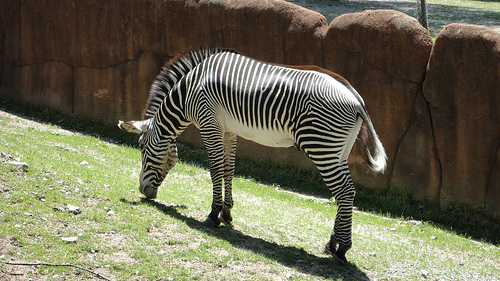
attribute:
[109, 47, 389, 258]
zebra — grazing, alone, black, white, eating, standing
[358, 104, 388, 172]
tail — fuzzy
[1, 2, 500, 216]
wall — brown, false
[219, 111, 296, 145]
belly — white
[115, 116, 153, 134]
ear — big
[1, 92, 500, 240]
shadow — dark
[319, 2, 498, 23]
fence — metal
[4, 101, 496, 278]
ground — green, patchy